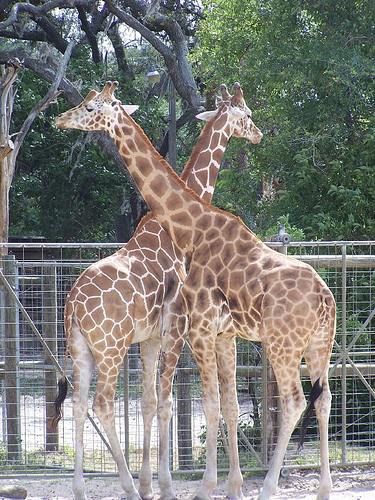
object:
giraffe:
[55, 81, 263, 499]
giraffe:
[53, 79, 336, 498]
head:
[53, 81, 140, 132]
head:
[195, 81, 263, 143]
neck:
[108, 117, 208, 259]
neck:
[182, 128, 235, 204]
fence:
[0, 232, 375, 479]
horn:
[102, 81, 112, 97]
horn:
[112, 81, 120, 96]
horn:
[220, 84, 227, 100]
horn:
[231, 82, 243, 100]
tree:
[0, 0, 375, 242]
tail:
[295, 297, 337, 455]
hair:
[296, 378, 325, 458]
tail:
[46, 302, 71, 431]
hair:
[47, 377, 67, 434]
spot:
[134, 155, 152, 177]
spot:
[165, 194, 188, 211]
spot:
[173, 227, 193, 249]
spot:
[220, 241, 237, 268]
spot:
[229, 270, 247, 286]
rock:
[0, 485, 27, 498]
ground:
[0, 351, 374, 499]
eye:
[86, 106, 94, 112]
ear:
[122, 105, 140, 117]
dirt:
[0, 395, 374, 499]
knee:
[157, 396, 173, 421]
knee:
[141, 396, 157, 420]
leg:
[189, 326, 220, 499]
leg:
[216, 335, 243, 499]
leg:
[261, 346, 306, 499]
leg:
[305, 353, 334, 499]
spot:
[208, 133, 220, 150]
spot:
[127, 294, 148, 323]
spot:
[91, 307, 105, 327]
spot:
[91, 273, 113, 292]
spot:
[144, 221, 161, 235]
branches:
[0, 1, 205, 121]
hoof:
[225, 496, 242, 499]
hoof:
[189, 495, 218, 499]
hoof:
[158, 495, 179, 499]